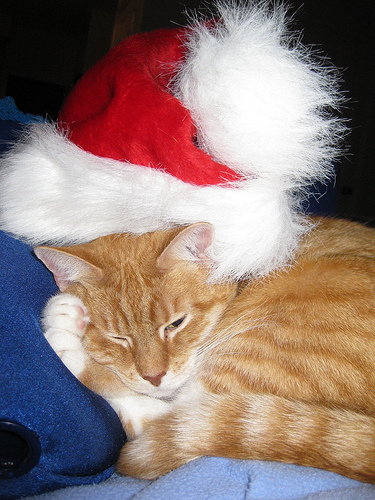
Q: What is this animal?
A: A cat.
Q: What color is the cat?
A: Orange and white.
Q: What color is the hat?
A: Red and white.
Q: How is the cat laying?
A: On its side.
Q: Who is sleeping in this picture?
A: The cat.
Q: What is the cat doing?
A: Sleeping.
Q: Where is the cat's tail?
A: In front.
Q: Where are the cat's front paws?
A: Under it's cheek.